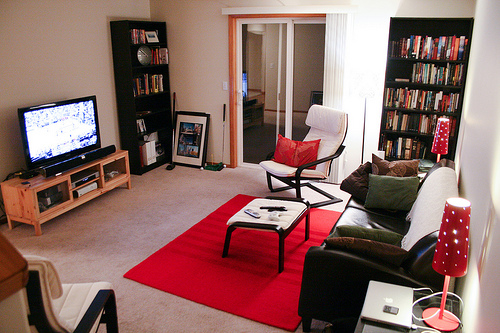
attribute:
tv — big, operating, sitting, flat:
[15, 93, 109, 170]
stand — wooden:
[0, 146, 136, 237]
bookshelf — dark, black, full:
[110, 16, 177, 175]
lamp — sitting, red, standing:
[422, 196, 475, 332]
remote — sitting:
[240, 204, 264, 219]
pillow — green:
[362, 171, 417, 211]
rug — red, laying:
[118, 192, 350, 332]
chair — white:
[262, 101, 350, 209]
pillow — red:
[270, 133, 322, 171]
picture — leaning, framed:
[172, 111, 210, 170]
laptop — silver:
[360, 275, 416, 330]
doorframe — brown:
[227, 12, 327, 170]